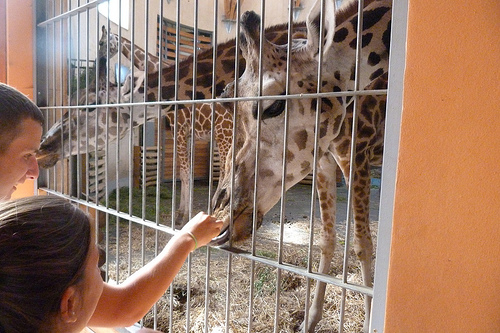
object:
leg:
[293, 151, 337, 332]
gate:
[156, 14, 215, 72]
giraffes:
[94, 25, 236, 230]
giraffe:
[207, 0, 396, 332]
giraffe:
[31, 20, 318, 172]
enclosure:
[0, 0, 497, 330]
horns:
[236, 10, 274, 67]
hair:
[0, 82, 44, 155]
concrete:
[198, 175, 378, 251]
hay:
[111, 215, 381, 332]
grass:
[66, 179, 380, 333]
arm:
[19, 230, 198, 329]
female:
[0, 194, 105, 332]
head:
[206, 9, 343, 248]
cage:
[30, 0, 411, 330]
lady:
[0, 193, 106, 331]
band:
[178, 229, 198, 253]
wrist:
[165, 230, 196, 256]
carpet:
[201, 9, 345, 255]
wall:
[369, 0, 500, 333]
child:
[0, 193, 104, 333]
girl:
[0, 185, 95, 333]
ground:
[83, 180, 380, 333]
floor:
[105, 226, 364, 326]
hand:
[172, 211, 223, 252]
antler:
[234, 9, 286, 76]